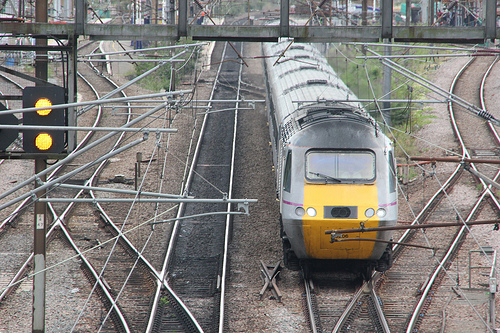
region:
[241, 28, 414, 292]
silver and yellow train on tracks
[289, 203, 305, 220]
round headlight on train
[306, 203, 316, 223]
round headlight on train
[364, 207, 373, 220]
round headlight on train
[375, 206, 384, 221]
round headlight on train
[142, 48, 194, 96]
grass growing by tracks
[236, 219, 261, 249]
gravel in between tracks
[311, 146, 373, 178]
windshield on front of train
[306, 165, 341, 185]
windshield wiper on train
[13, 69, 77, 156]
yellow signal on left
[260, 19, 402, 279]
A long grey and yellow train.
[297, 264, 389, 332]
Silver tracks in front of a train.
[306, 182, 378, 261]
Yellow on the front of a train.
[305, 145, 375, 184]
Large windshield on a train.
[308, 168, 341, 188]
Black windshield wiper on a train.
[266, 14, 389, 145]
A silver train roof.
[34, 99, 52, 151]
Two round illuminated yellow lights.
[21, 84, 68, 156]
A black traffic light with two yellow round lights.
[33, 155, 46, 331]
A brown and grey pole holding up a black light.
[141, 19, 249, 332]
Very straight silver tracks with black on the ground inside them.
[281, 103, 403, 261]
front part of the train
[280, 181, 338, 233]
light of the train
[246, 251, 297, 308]
a iron stand on track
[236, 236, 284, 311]
a tool beside train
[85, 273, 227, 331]
two tracks joining at one point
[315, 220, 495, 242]
a pole on the side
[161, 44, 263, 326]
a long rail way track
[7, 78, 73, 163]
a signal board in top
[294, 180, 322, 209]
edge of a train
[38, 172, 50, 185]
part of a light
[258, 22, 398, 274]
A long grey and yellow train.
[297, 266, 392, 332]
Silver and brown tracks in front of a train.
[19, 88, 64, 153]
A black traffic light with two yellow lights illuminated.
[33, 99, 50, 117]
Top round illuminated yellow light.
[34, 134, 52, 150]
Bottom yellow round light.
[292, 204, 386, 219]
Four oval lights on the front of a train with 2 illuminated.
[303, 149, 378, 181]
Large double front train windshield.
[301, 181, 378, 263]
Yellow front of a grey train.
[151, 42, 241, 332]
Very straight silver tracks with black in the middle.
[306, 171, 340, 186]
Black windshield wipers on the front windshield on a train.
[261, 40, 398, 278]
yellow and silver train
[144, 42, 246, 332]
train tracks going straight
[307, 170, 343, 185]
windshield wiper on train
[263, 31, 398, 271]
large long yellow and silver train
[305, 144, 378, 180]
large wide clear glass window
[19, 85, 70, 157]
large black and yellow light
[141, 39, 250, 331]
long wide metal track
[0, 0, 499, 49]
long wide metal rail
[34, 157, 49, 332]
tall thin metal pole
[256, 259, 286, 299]
cross loose brown track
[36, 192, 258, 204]
long silver thin metal pole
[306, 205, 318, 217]
small round white light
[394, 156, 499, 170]
long thin round red pole